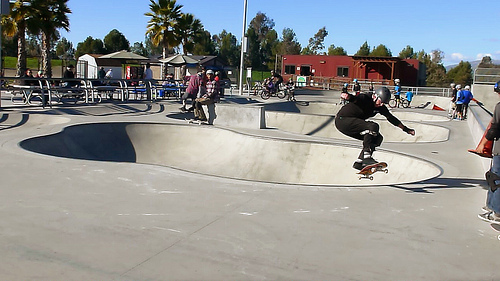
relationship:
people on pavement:
[177, 68, 218, 122] [0, 88, 498, 278]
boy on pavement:
[453, 84, 464, 121] [0, 88, 498, 278]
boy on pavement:
[453, 84, 464, 121] [2, 186, 477, 276]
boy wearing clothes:
[335, 87, 415, 181] [337, 87, 411, 156]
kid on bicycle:
[393, 79, 403, 108] [388, 95, 410, 108]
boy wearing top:
[403, 85, 414, 105] [454, 84, 467, 105]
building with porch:
[281, 54, 427, 95] [359, 60, 393, 90]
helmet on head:
[372, 83, 392, 103] [369, 82, 394, 108]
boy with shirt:
[335, 87, 415, 181] [179, 72, 202, 92]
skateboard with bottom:
[356, 160, 388, 180] [366, 160, 386, 173]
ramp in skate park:
[20, 117, 440, 189] [0, 85, 497, 277]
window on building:
[333, 60, 347, 75] [275, 50, 427, 100]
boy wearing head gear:
[335, 87, 415, 181] [373, 83, 391, 105]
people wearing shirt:
[192, 70, 220, 125] [199, 70, 221, 98]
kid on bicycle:
[391, 74, 406, 106] [388, 92, 411, 106]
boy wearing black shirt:
[335, 87, 415, 181] [340, 91, 405, 123]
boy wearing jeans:
[335, 87, 415, 181] [331, 114, 385, 156]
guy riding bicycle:
[268, 69, 283, 84] [260, 81, 288, 99]